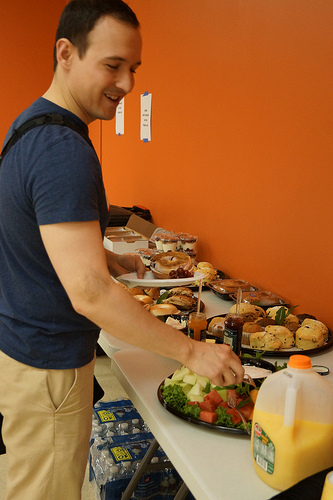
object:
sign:
[140, 92, 152, 143]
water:
[119, 421, 128, 434]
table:
[104, 219, 332, 499]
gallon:
[248, 349, 331, 495]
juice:
[249, 411, 333, 488]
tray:
[157, 359, 280, 435]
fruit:
[203, 411, 213, 421]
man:
[3, 0, 244, 499]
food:
[158, 363, 258, 433]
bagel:
[150, 250, 194, 275]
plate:
[118, 270, 205, 290]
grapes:
[169, 270, 176, 278]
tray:
[198, 307, 331, 358]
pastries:
[295, 325, 324, 348]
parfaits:
[180, 236, 198, 252]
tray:
[119, 286, 205, 326]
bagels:
[150, 301, 181, 318]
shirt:
[1, 95, 112, 368]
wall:
[139, 4, 331, 330]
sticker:
[252, 420, 276, 475]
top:
[287, 353, 314, 374]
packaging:
[93, 464, 124, 487]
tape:
[142, 138, 148, 144]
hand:
[196, 337, 244, 393]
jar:
[223, 316, 243, 354]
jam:
[223, 316, 241, 360]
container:
[230, 289, 293, 308]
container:
[206, 278, 258, 299]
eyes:
[104, 63, 118, 69]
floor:
[99, 370, 115, 394]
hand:
[112, 251, 150, 281]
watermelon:
[205, 390, 222, 402]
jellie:
[188, 310, 207, 342]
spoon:
[197, 280, 203, 314]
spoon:
[235, 288, 242, 316]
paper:
[115, 96, 125, 136]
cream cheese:
[173, 320, 178, 325]